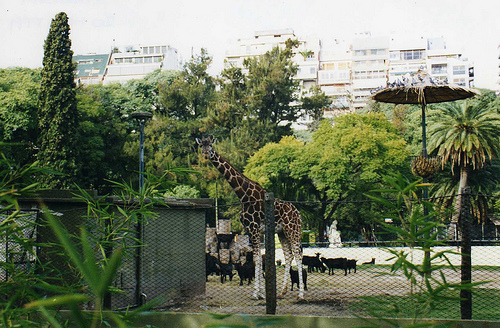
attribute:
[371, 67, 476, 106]
umbrella — straw, black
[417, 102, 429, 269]
pole — metal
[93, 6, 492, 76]
sky — overcast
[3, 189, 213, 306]
shed — small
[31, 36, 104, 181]
tree — tall, green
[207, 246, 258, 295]
goats — black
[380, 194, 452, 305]
plant — green, leafy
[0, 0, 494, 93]
sky — hazy, grey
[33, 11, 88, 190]
leaves — green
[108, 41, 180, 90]
building — tall, multi story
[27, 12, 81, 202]
tree — tall, thin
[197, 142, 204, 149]
eye — black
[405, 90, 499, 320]
tree — palm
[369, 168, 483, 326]
plant — green, thin